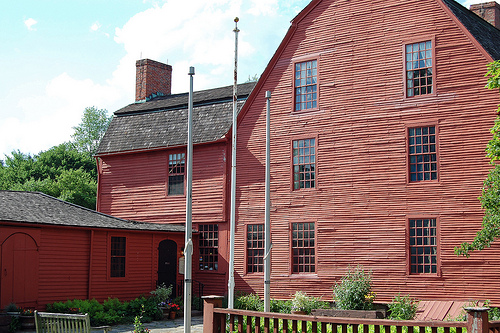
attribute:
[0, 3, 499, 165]
sky — blue, clear, cloudy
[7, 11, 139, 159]
some clouds — white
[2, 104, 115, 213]
leaves — green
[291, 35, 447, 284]
several windows — closed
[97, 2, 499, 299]
wall — brown, made of bamboo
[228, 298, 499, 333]
grass — green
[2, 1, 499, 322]
barn house — old, reddish brown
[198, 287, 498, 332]
fence — wooden, red, brown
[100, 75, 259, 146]
rooftop — black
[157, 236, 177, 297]
coal door — old, black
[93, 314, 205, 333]
walkway — made from cobbleston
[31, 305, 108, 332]
park bench — brown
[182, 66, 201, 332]
pole — white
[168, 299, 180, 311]
flower — red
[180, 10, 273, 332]
poles — white